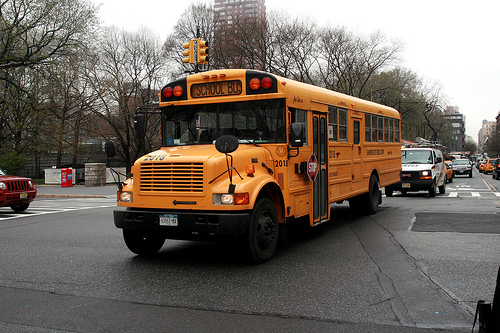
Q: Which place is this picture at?
A: It is at the street.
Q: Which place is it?
A: It is a street.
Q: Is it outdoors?
A: Yes, it is outdoors.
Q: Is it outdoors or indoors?
A: It is outdoors.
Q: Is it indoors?
A: No, it is outdoors.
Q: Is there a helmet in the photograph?
A: No, there are no helmets.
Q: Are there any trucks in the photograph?
A: No, there are no trucks.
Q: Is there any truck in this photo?
A: No, there are no trucks.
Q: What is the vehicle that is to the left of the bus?
A: The vehicle is a car.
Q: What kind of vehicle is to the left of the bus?
A: The vehicle is a car.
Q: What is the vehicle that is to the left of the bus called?
A: The vehicle is a car.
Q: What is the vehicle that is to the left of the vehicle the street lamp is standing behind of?
A: The vehicle is a car.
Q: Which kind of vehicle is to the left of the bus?
A: The vehicle is a car.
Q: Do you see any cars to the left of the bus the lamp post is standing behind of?
A: Yes, there is a car to the left of the bus.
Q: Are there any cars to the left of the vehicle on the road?
A: Yes, there is a car to the left of the bus.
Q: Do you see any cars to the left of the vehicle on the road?
A: Yes, there is a car to the left of the bus.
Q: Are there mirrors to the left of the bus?
A: No, there is a car to the left of the bus.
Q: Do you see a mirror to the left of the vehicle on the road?
A: No, there is a car to the left of the bus.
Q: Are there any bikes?
A: No, there are no bikes.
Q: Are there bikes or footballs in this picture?
A: No, there are no bikes or footballs.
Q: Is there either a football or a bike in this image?
A: No, there are no bikes or footballs.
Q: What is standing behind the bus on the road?
A: The street light is standing behind the bus.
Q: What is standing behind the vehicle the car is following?
A: The street light is standing behind the bus.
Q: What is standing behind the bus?
A: The street light is standing behind the bus.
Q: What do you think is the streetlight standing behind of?
A: The streetlight is standing behind the bus.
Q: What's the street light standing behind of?
A: The streetlight is standing behind the bus.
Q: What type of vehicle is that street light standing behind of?
A: The street light is standing behind the bus.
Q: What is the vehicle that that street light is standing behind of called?
A: The vehicle is a bus.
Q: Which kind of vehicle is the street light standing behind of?
A: The street light is standing behind the bus.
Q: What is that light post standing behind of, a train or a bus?
A: The light post is standing behind a bus.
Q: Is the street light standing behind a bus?
A: Yes, the street light is standing behind a bus.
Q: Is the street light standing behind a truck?
A: No, the street light is standing behind a bus.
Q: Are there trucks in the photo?
A: No, there are no trucks.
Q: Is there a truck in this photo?
A: No, there are no trucks.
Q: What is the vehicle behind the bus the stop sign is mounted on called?
A: The vehicle is a car.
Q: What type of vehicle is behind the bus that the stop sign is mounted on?
A: The vehicle is a car.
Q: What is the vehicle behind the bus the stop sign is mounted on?
A: The vehicle is a car.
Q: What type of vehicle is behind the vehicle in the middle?
A: The vehicle is a car.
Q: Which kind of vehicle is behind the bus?
A: The vehicle is a car.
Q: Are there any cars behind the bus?
A: Yes, there is a car behind the bus.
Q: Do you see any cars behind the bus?
A: Yes, there is a car behind the bus.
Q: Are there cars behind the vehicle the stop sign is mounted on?
A: Yes, there is a car behind the bus.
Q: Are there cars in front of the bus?
A: No, the car is behind the bus.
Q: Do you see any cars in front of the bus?
A: No, the car is behind the bus.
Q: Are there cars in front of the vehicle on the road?
A: No, the car is behind the bus.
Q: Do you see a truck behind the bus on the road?
A: No, there is a car behind the bus.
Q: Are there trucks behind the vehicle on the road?
A: No, there is a car behind the bus.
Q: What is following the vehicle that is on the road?
A: The car is following the bus.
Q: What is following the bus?
A: The car is following the bus.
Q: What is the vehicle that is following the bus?
A: The vehicle is a car.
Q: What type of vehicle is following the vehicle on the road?
A: The vehicle is a car.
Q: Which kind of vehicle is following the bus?
A: The vehicle is a car.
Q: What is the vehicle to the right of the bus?
A: The vehicle is a car.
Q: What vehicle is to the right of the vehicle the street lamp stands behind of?
A: The vehicle is a car.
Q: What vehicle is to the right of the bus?
A: The vehicle is a car.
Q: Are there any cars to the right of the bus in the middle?
A: Yes, there is a car to the right of the bus.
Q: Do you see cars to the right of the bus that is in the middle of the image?
A: Yes, there is a car to the right of the bus.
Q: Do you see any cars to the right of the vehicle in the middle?
A: Yes, there is a car to the right of the bus.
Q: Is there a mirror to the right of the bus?
A: No, there is a car to the right of the bus.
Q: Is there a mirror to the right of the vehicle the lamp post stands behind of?
A: No, there is a car to the right of the bus.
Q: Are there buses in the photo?
A: Yes, there is a bus.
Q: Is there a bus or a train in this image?
A: Yes, there is a bus.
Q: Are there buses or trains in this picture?
A: Yes, there is a bus.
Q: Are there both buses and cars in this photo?
A: Yes, there are both a bus and a car.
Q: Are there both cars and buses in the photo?
A: Yes, there are both a bus and a car.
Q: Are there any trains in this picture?
A: No, there are no trains.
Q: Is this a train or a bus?
A: This is a bus.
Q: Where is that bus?
A: The bus is on the road.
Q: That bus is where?
A: The bus is on the road.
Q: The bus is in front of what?
A: The bus is in front of the car.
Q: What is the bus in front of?
A: The bus is in front of the car.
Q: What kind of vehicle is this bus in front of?
A: The bus is in front of the car.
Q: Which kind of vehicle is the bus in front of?
A: The bus is in front of the car.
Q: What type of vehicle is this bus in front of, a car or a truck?
A: The bus is in front of a car.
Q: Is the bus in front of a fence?
A: No, the bus is in front of the car.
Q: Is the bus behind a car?
A: No, the bus is in front of a car.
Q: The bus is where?
A: The bus is on the road.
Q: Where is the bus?
A: The bus is on the road.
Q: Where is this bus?
A: The bus is on the road.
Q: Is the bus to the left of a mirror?
A: No, the bus is to the left of the car.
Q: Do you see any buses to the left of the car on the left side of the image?
A: No, the bus is to the right of the car.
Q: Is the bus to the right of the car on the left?
A: Yes, the bus is to the right of the car.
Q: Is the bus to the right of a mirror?
A: No, the bus is to the right of the car.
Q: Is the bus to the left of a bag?
A: No, the bus is to the left of a car.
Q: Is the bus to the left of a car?
A: Yes, the bus is to the left of a car.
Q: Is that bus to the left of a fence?
A: No, the bus is to the left of a car.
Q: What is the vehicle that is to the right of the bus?
A: The vehicle is a car.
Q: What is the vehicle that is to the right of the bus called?
A: The vehicle is a car.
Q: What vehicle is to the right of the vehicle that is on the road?
A: The vehicle is a car.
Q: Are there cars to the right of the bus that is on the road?
A: Yes, there is a car to the right of the bus.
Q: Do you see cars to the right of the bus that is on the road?
A: Yes, there is a car to the right of the bus.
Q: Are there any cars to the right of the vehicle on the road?
A: Yes, there is a car to the right of the bus.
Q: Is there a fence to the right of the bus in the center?
A: No, there is a car to the right of the bus.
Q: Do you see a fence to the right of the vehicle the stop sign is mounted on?
A: No, there is a car to the right of the bus.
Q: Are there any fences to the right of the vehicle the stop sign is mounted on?
A: No, there is a car to the right of the bus.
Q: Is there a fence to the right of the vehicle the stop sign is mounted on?
A: No, there is a car to the right of the bus.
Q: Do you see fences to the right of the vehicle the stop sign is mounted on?
A: No, there is a car to the right of the bus.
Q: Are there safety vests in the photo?
A: No, there are no safety vests.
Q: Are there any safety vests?
A: No, there are no safety vests.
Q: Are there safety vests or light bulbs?
A: No, there are no safety vests or light bulbs.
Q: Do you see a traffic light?
A: Yes, there is a traffic light.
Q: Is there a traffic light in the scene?
A: Yes, there is a traffic light.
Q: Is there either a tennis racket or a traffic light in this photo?
A: Yes, there is a traffic light.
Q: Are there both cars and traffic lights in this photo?
A: Yes, there are both a traffic light and cars.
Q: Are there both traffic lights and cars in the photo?
A: Yes, there are both a traffic light and cars.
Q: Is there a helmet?
A: No, there are no helmets.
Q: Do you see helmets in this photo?
A: No, there are no helmets.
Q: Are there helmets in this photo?
A: No, there are no helmets.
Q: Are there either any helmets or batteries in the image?
A: No, there are no helmets or batteries.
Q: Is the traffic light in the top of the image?
A: Yes, the traffic light is in the top of the image.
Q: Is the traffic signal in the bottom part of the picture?
A: No, the traffic signal is in the top of the image.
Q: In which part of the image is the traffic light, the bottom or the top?
A: The traffic light is in the top of the image.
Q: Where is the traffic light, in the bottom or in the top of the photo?
A: The traffic light is in the top of the image.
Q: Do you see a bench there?
A: No, there are no benches.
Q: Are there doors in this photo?
A: Yes, there is a door.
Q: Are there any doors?
A: Yes, there is a door.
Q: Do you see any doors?
A: Yes, there is a door.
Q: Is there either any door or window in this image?
A: Yes, there is a door.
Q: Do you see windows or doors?
A: Yes, there is a door.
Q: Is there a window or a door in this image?
A: Yes, there is a door.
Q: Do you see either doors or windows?
A: Yes, there is a door.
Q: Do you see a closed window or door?
A: Yes, there is a closed door.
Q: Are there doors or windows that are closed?
A: Yes, the door is closed.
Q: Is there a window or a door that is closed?
A: Yes, the door is closed.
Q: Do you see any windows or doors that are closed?
A: Yes, the door is closed.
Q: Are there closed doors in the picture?
A: Yes, there is a closed door.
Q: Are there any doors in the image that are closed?
A: Yes, there is a door that is closed.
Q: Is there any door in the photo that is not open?
A: Yes, there is an closed door.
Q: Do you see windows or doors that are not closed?
A: No, there is a door but it is closed.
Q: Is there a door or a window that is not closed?
A: No, there is a door but it is closed.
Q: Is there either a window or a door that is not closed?
A: No, there is a door but it is closed.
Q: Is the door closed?
A: Yes, the door is closed.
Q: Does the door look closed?
A: Yes, the door is closed.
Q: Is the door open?
A: No, the door is closed.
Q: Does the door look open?
A: No, the door is closed.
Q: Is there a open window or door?
A: No, there is a door but it is closed.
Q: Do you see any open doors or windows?
A: No, there is a door but it is closed.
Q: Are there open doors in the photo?
A: No, there is a door but it is closed.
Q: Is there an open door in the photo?
A: No, there is a door but it is closed.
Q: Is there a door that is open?
A: No, there is a door but it is closed.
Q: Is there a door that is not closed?
A: No, there is a door but it is closed.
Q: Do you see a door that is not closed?
A: No, there is a door but it is closed.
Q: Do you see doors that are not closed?
A: No, there is a door but it is closed.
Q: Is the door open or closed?
A: The door is closed.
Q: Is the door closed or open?
A: The door is closed.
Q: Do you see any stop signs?
A: Yes, there is a stop sign.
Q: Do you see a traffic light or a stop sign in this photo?
A: Yes, there is a stop sign.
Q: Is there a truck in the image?
A: No, there are no trucks.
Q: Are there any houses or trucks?
A: No, there are no trucks or houses.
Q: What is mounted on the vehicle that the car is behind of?
A: The stop sign is mounted on the bus.